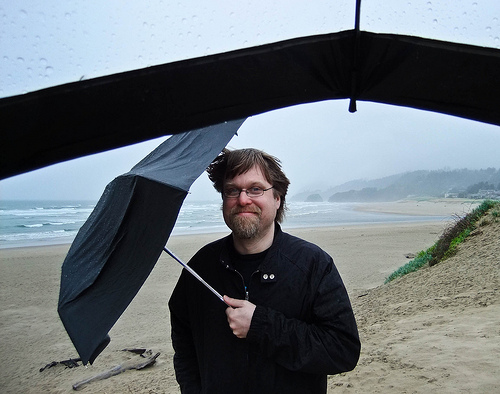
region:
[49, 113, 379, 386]
man with umbrella in hand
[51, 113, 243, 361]
umbrella in man's hand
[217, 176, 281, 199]
glasses on man's face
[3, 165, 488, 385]
beach area where man is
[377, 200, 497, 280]
grassy area on sand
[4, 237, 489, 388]
sand area of beach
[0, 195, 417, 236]
water area of beach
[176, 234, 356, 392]
jacket on a man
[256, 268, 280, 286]
buttons on man's jacket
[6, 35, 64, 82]
drops of rain on surface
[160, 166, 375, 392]
the man has glasses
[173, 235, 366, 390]
the jacket is black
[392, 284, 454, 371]
footprints are on the sand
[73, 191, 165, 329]
the umbrella is black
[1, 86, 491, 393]
it is raining outside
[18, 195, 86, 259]
the ocean is in the background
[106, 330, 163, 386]
scrap metal is on the beach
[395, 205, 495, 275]
grasss has grown on the sand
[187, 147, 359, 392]
the man is smiling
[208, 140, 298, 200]
the hair is brown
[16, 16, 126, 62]
Sky is blue color.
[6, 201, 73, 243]
water is blue color.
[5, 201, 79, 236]
Waves are white color.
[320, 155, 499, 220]
Hills are behind the man.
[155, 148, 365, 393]
Man is standing in the sand.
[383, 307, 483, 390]
Sand is brown color.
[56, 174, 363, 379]
Man is holding umbrella.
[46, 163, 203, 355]
Umbrella is black color.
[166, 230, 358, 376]
Man is wearing black shirt.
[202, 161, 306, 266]
man is wearing eyeglass.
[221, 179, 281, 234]
man wearing glasses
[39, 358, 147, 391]
old wood on the beach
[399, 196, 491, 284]
grass growing on the dune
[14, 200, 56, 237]
waves crashing to shore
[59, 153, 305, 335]
man holding an umbrella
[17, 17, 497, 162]
umbrella in the top of the picture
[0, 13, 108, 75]
rain drops on the clear part of the umbrella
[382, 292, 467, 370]
beach sand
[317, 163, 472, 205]
hills in the distance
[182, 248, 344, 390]
man wearing a black jacket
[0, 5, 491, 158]
the edge of a clear umbrella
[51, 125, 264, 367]
a wrinkled black umbrella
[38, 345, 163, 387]
a few pieces of driftwood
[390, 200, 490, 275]
a few plants growing in the sand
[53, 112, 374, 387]
a man holding an umbrella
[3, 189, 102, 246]
a few waves crashing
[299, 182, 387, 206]
a few distant rock formations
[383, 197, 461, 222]
a steep beach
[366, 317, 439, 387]
some footprints in the sand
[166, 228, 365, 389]
a black rain jacket